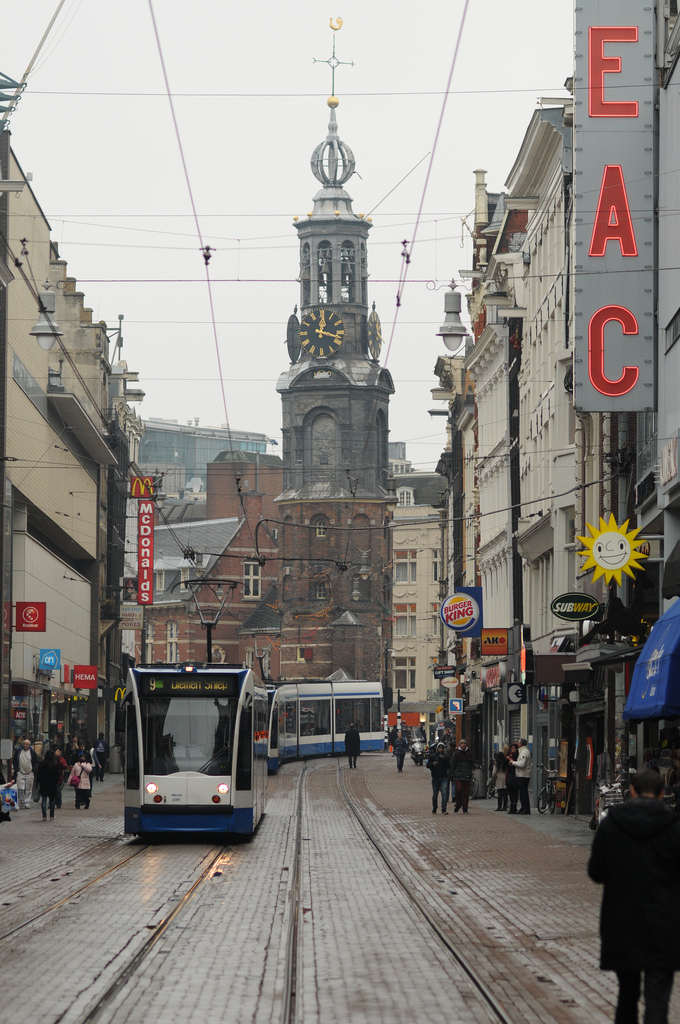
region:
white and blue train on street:
[118, 654, 392, 841]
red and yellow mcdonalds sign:
[105, 474, 156, 497]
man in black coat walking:
[574, 769, 677, 1021]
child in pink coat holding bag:
[68, 751, 97, 810]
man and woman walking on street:
[428, 738, 475, 820]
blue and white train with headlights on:
[117, 657, 257, 840]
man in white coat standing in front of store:
[506, 738, 552, 814]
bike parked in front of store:
[536, 762, 583, 817]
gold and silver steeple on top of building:
[302, 14, 359, 224]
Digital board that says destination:
[143, 675, 233, 692]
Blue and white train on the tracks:
[126, 664, 382, 837]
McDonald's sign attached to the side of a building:
[132, 473, 156, 606]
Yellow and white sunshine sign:
[578, 515, 646, 586]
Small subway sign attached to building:
[550, 592, 596, 619]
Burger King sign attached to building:
[442, 585, 479, 637]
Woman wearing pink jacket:
[68, 755, 91, 809]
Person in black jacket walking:
[586, 767, 677, 1021]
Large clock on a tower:
[299, 310, 343, 356]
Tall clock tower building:
[275, 13, 392, 502]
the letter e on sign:
[567, 8, 662, 125]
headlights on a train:
[134, 765, 248, 804]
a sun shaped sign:
[572, 497, 655, 592]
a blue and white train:
[111, 654, 433, 883]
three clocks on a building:
[266, 302, 392, 369]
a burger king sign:
[429, 574, 495, 646]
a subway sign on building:
[545, 588, 603, 625]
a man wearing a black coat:
[597, 796, 664, 976]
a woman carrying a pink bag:
[63, 771, 85, 790]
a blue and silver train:
[127, 656, 374, 845]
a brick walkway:
[446, 819, 559, 908]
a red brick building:
[173, 509, 267, 668]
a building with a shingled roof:
[175, 507, 249, 593]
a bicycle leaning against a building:
[533, 762, 570, 814]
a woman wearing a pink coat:
[75, 757, 86, 793]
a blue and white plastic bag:
[2, 774, 25, 815]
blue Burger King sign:
[438, 590, 482, 634]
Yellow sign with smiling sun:
[573, 513, 645, 585]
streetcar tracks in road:
[284, 758, 499, 1012]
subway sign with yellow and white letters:
[544, 590, 602, 623]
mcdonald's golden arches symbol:
[128, 469, 154, 500]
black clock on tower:
[296, 308, 344, 362]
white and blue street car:
[113, 651, 394, 847]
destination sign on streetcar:
[168, 670, 233, 696]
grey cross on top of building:
[306, 31, 356, 99]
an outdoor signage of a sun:
[568, 516, 648, 583]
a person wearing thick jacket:
[425, 736, 450, 787]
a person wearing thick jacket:
[450, 737, 474, 782]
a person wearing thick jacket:
[513, 731, 537, 785]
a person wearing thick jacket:
[580, 766, 678, 975]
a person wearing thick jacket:
[38, 743, 64, 795]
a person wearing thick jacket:
[68, 753, 96, 794]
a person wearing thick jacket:
[385, 731, 410, 770]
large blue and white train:
[121, 657, 391, 841]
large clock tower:
[261, 16, 398, 726]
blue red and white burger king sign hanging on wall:
[435, 584, 484, 639]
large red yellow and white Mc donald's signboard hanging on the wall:
[126, 469, 163, 608]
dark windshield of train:
[124, 682, 255, 791]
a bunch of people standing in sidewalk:
[13, 701, 679, 1014]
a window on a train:
[140, 676, 230, 778]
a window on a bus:
[235, 695, 245, 797]